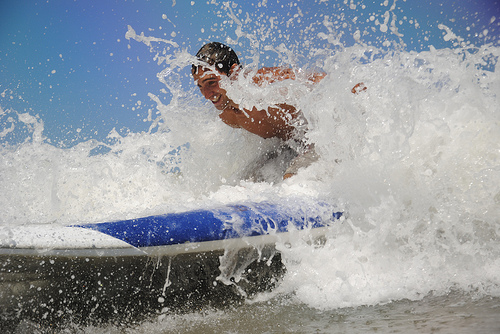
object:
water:
[3, 14, 498, 330]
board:
[1, 198, 344, 249]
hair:
[192, 41, 243, 74]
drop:
[109, 53, 113, 56]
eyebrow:
[202, 77, 217, 83]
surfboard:
[0, 196, 345, 249]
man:
[189, 41, 367, 182]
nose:
[205, 87, 214, 98]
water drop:
[51, 70, 57, 74]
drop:
[124, 24, 142, 42]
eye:
[208, 81, 216, 86]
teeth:
[212, 95, 221, 102]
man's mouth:
[210, 94, 222, 105]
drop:
[92, 42, 96, 45]